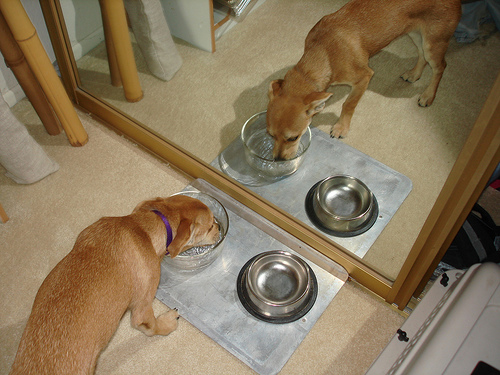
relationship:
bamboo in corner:
[1, 1, 91, 146] [6, 1, 136, 199]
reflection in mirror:
[163, 7, 466, 234] [41, 1, 499, 309]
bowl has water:
[236, 252, 317, 325] [259, 266, 300, 300]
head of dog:
[135, 197, 223, 249] [12, 196, 221, 372]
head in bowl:
[135, 197, 223, 249] [158, 191, 229, 269]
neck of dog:
[127, 205, 181, 264] [12, 196, 221, 372]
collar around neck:
[149, 205, 176, 258] [127, 205, 181, 264]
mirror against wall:
[41, 1, 499, 309] [0, 2, 57, 109]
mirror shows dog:
[41, 1, 499, 309] [12, 196, 221, 372]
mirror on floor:
[41, 1, 499, 309] [1, 92, 412, 372]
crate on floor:
[364, 261, 500, 374] [1, 92, 412, 372]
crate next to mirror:
[364, 261, 500, 374] [41, 1, 499, 309]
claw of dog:
[156, 307, 181, 336] [12, 196, 221, 372]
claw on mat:
[156, 307, 183, 330] [138, 179, 351, 374]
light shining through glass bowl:
[219, 136, 290, 188] [242, 111, 312, 177]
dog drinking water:
[12, 196, 221, 372] [171, 243, 225, 271]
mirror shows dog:
[41, 1, 499, 309] [264, 2, 461, 163]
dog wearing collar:
[12, 196, 221, 372] [149, 205, 176, 258]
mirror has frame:
[41, 1, 499, 309] [386, 1, 499, 313]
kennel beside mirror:
[364, 261, 500, 374] [41, 1, 499, 309]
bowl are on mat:
[236, 252, 317, 325] [138, 179, 351, 374]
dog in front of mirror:
[12, 196, 221, 372] [41, 1, 499, 309]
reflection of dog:
[264, 2, 461, 163] [12, 196, 221, 372]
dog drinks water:
[12, 196, 221, 372] [171, 243, 225, 271]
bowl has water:
[158, 191, 229, 269] [171, 243, 225, 271]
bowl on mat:
[236, 252, 317, 325] [138, 179, 351, 374]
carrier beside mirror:
[364, 261, 500, 374] [41, 1, 499, 309]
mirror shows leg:
[41, 1, 499, 309] [331, 66, 375, 140]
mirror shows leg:
[41, 1, 499, 309] [399, 26, 428, 84]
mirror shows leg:
[41, 1, 499, 309] [416, 37, 453, 110]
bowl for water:
[158, 191, 229, 269] [171, 243, 225, 271]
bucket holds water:
[158, 191, 229, 269] [171, 243, 225, 271]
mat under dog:
[138, 179, 351, 374] [12, 196, 221, 372]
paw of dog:
[156, 307, 181, 336] [12, 196, 221, 372]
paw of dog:
[329, 120, 352, 139] [12, 196, 221, 372]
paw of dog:
[416, 90, 438, 109] [12, 196, 221, 372]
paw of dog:
[399, 65, 422, 87] [12, 196, 221, 372]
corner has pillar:
[41, 1, 149, 108] [103, 2, 145, 101]